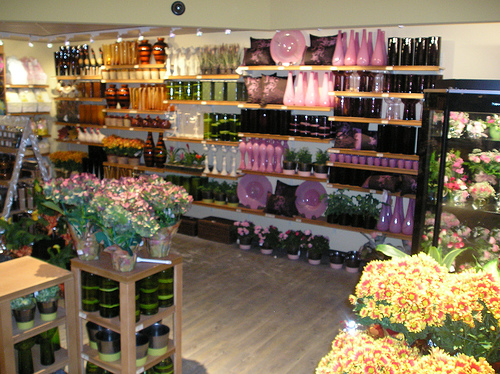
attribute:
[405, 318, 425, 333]
flower — yellow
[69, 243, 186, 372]
table — square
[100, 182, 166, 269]
plant — pink 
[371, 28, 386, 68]
vase — pink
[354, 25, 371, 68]
vase — pink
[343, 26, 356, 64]
vase — pink, long 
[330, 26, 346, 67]
vase — pink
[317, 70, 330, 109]
vase — pink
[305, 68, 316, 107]
vase — pink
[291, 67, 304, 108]
vase — pink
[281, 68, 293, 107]
vase — pink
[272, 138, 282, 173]
vase — pink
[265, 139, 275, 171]
vase — pink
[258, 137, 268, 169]
vase — pink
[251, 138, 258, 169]
vase — pink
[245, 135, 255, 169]
vase — pink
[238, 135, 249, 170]
vase — pink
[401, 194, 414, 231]
vase — pink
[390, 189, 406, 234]
vase — pink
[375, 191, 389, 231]
vase — pink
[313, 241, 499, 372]
flowers — red, yellow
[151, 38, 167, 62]
vase — black, orange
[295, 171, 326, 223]
plate — purple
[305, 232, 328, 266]
flower — potted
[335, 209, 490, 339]
flowers — orange, yellow, bunched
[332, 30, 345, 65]
vase — pink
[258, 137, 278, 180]
vase — pink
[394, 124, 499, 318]
case — cold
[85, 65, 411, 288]
shelves — wood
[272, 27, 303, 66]
plate — pink